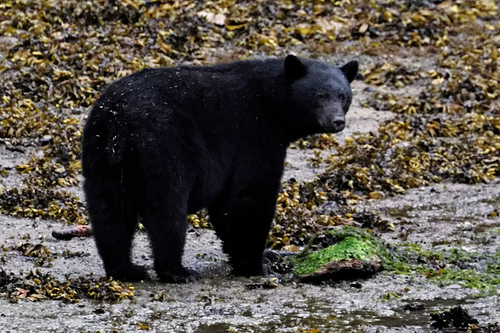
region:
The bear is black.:
[72, 57, 283, 248]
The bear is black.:
[71, 77, 202, 204]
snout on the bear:
[330, 116, 352, 131]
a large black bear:
[65, 53, 363, 300]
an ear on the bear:
[342, 55, 368, 85]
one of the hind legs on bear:
[146, 201, 193, 286]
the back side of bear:
[97, 93, 167, 166]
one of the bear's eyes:
[316, 88, 332, 102]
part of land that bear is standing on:
[179, 303, 314, 331]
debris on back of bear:
[93, 88, 178, 145]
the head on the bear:
[266, 43, 365, 138]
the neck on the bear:
[283, 120, 326, 144]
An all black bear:
[71, 25, 371, 287]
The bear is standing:
[86, 36, 357, 297]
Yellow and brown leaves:
[8, 4, 495, 263]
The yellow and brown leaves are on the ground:
[0, 5, 485, 250]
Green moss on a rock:
[276, 237, 442, 283]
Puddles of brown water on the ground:
[184, 280, 485, 322]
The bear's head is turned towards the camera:
[79, 43, 425, 293]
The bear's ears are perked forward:
[253, 41, 375, 140]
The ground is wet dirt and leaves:
[8, 72, 486, 322]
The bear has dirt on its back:
[72, 51, 251, 181]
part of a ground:
[433, 204, 485, 259]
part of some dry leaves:
[380, 157, 427, 184]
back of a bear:
[86, 130, 173, 235]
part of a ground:
[348, 273, 414, 328]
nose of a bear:
[332, 115, 349, 137]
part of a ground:
[375, 271, 413, 301]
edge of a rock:
[324, 265, 386, 276]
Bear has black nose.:
[325, 113, 351, 132]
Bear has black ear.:
[283, 47, 328, 104]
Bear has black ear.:
[332, 46, 384, 109]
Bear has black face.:
[311, 66, 372, 171]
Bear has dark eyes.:
[315, 96, 356, 113]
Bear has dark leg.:
[218, 192, 295, 262]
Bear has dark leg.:
[106, 217, 118, 225]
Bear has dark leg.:
[145, 223, 225, 305]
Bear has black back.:
[98, 55, 305, 132]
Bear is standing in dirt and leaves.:
[89, 217, 344, 316]